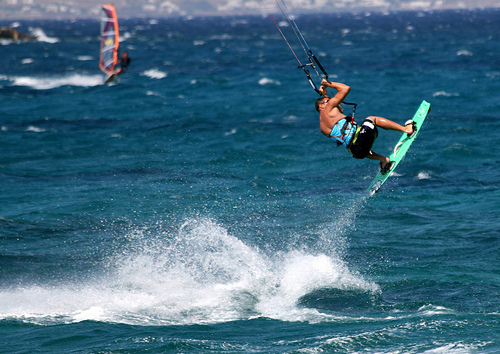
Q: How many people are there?
A: 2.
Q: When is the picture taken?
A: Daytime.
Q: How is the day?
A: Sunny.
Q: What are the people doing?
A: Wakeboarding.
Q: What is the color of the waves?
A: White.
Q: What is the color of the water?
A: Blue.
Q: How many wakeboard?
A: Two.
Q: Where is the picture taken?
A: At the ocean.